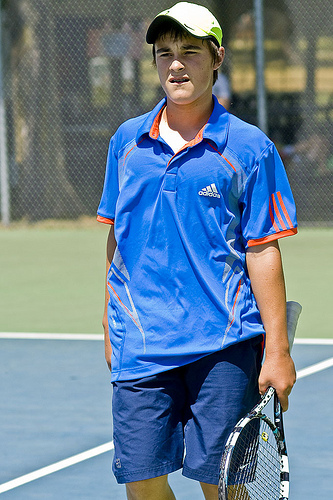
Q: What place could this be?
A: It is a pavement.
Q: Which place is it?
A: It is a pavement.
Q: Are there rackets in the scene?
A: Yes, there is a racket.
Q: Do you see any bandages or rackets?
A: Yes, there is a racket.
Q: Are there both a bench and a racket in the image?
A: No, there is a racket but no benches.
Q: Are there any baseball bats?
A: No, there are no baseball bats.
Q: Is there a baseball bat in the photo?
A: No, there are no baseball bats.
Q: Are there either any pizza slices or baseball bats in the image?
A: No, there are no baseball bats or pizza slices.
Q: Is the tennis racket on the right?
A: Yes, the tennis racket is on the right of the image.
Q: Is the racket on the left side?
A: No, the racket is on the right of the image.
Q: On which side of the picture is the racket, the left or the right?
A: The racket is on the right of the image.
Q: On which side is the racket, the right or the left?
A: The racket is on the right of the image.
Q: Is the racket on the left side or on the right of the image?
A: The racket is on the right of the image.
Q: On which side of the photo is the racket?
A: The racket is on the right of the image.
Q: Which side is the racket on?
A: The racket is on the right of the image.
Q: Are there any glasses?
A: No, there are no glasses.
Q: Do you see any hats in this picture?
A: Yes, there is a hat.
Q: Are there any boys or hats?
A: Yes, there is a hat.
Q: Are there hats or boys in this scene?
A: Yes, there is a hat.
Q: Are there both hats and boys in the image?
A: Yes, there are both a hat and a boy.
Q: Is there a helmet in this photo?
A: No, there are no helmets.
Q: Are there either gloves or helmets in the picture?
A: No, there are no helmets or gloves.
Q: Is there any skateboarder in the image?
A: No, there are no skateboarders.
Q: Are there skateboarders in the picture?
A: No, there are no skateboarders.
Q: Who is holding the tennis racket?
A: The boy is holding the tennis racket.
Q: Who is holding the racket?
A: The boy is holding the tennis racket.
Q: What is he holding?
A: The boy is holding the racket.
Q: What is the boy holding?
A: The boy is holding the racket.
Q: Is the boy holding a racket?
A: Yes, the boy is holding a racket.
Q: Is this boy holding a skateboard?
A: No, the boy is holding a racket.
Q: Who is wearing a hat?
A: The boy is wearing a hat.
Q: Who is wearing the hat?
A: The boy is wearing a hat.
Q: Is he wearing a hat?
A: Yes, the boy is wearing a hat.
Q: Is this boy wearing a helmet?
A: No, the boy is wearing a hat.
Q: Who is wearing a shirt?
A: The boy is wearing a shirt.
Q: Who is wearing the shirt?
A: The boy is wearing a shirt.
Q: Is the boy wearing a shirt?
A: Yes, the boy is wearing a shirt.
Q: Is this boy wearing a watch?
A: No, the boy is wearing a shirt.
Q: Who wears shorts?
A: The boy wears shorts.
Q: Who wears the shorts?
A: The boy wears shorts.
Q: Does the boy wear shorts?
A: Yes, the boy wears shorts.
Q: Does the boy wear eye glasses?
A: No, the boy wears shorts.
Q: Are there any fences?
A: Yes, there is a fence.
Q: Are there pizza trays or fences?
A: Yes, there is a fence.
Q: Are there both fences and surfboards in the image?
A: No, there is a fence but no surfboards.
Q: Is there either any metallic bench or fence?
A: Yes, there is a metal fence.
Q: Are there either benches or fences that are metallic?
A: Yes, the fence is metallic.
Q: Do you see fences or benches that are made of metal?
A: Yes, the fence is made of metal.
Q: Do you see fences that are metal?
A: Yes, there is a metal fence.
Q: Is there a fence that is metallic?
A: Yes, there is a fence that is metallic.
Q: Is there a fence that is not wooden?
A: Yes, there is a metallic fence.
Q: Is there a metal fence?
A: Yes, there is a fence that is made of metal.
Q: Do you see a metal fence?
A: Yes, there is a fence that is made of metal.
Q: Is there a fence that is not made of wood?
A: Yes, there is a fence that is made of metal.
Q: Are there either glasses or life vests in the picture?
A: No, there are no glasses or life vests.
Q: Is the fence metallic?
A: Yes, the fence is metallic.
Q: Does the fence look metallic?
A: Yes, the fence is metallic.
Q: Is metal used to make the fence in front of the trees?
A: Yes, the fence is made of metal.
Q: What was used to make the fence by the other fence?
A: The fence is made of metal.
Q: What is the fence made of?
A: The fence is made of metal.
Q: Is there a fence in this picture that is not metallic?
A: No, there is a fence but it is metallic.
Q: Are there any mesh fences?
A: No, there is a fence but it is made of metal.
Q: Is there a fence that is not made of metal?
A: No, there is a fence but it is made of metal.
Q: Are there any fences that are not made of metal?
A: No, there is a fence but it is made of metal.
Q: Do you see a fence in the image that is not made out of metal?
A: No, there is a fence but it is made of metal.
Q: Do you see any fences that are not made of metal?
A: No, there is a fence but it is made of metal.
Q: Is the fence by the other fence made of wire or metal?
A: The fence is made of metal.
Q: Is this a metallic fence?
A: Yes, this is a metallic fence.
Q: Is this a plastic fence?
A: No, this is a metallic fence.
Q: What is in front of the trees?
A: The fence is in front of the trees.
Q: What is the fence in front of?
A: The fence is in front of the trees.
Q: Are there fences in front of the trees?
A: Yes, there is a fence in front of the trees.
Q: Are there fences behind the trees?
A: No, the fence is in front of the trees.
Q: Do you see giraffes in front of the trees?
A: No, there is a fence in front of the trees.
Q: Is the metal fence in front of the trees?
A: Yes, the fence is in front of the trees.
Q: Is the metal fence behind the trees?
A: No, the fence is in front of the trees.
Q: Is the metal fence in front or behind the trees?
A: The fence is in front of the trees.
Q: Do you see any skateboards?
A: No, there are no skateboards.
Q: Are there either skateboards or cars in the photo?
A: No, there are no skateboards or cars.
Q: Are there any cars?
A: No, there are no cars.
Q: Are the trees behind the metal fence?
A: Yes, the trees are behind the fence.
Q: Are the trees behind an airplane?
A: No, the trees are behind the fence.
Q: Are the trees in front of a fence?
A: No, the trees are behind a fence.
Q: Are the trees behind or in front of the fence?
A: The trees are behind the fence.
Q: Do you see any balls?
A: No, there are no balls.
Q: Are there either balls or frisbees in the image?
A: No, there are no balls or frisbees.